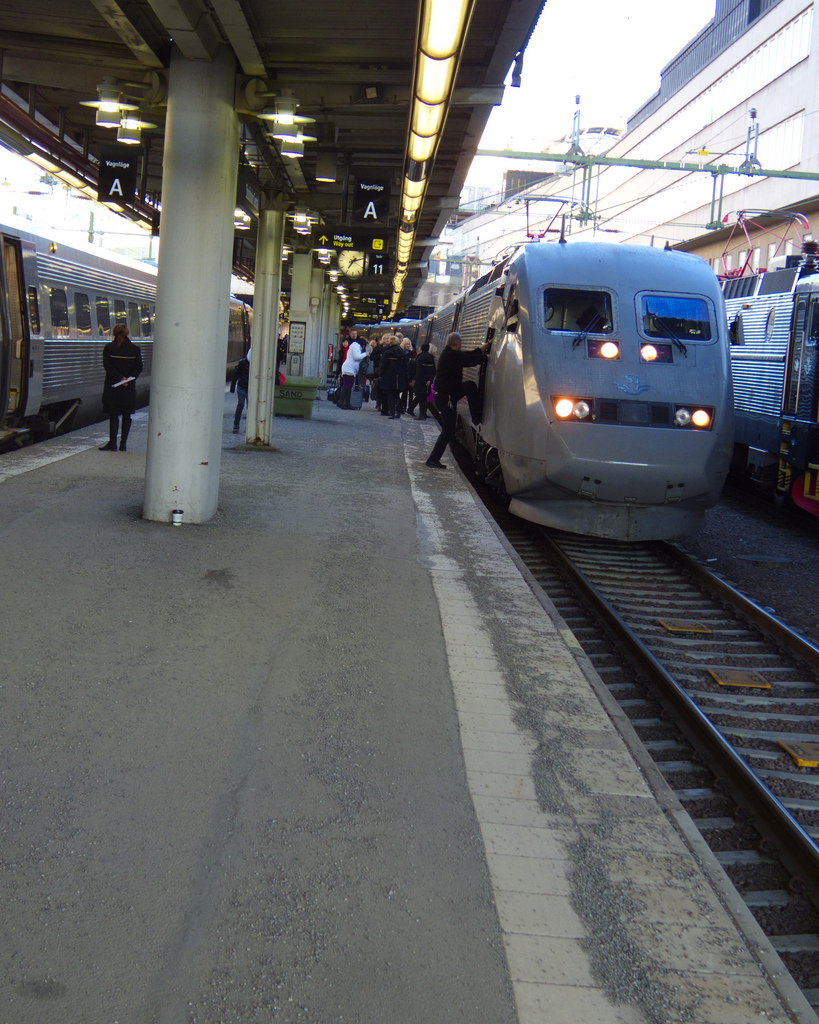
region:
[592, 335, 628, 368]
a headlight on the train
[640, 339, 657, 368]
a headlight on the train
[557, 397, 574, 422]
a headlight on the train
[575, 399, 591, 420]
a headlight on the train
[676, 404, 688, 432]
a headlight on the train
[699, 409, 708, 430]
a headlight on the train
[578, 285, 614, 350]
windshield wiper on train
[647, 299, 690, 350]
windshield wiper on train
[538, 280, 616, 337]
window on front train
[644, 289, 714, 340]
window on front train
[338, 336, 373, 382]
White sweater on a passenger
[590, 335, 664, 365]
Two headlights on the train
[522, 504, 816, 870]
Tracks in front of the train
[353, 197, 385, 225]
The letter A on a sign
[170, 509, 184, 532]
Cup next to the column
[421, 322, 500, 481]
Person boarding the train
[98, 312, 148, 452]
Person standing next to the train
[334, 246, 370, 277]
Clock hanging from ceiling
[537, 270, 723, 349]
Windshields on the train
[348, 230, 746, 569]
long silver train on train tracks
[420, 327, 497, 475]
person boarding train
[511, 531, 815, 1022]
train tracks in front of train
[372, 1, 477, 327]
long yellow light on ceiling of platform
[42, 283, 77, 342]
window on side of train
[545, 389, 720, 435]
headlights on front of train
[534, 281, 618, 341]
window on front of train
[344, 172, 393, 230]
black and white sign hanging from roof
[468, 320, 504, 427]
door on side of train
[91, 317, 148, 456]
person standing in platform dressed in black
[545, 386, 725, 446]
yellow headlights on front of train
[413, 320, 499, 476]
conductor boarding train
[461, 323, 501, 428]
door on side of train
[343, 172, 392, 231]
black and white sign hanging from ceiling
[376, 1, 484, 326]
long yellow light on ceiling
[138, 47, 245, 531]
white post column on train platform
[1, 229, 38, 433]
open door on train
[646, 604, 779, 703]
yellow square blocks on train tracks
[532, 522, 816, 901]
train rails for subway train to move along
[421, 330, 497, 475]
man hopping aboard train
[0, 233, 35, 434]
open door to subway train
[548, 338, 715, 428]
four headlight that are illuminated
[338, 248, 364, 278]
a clock at the train station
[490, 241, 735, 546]
a smooth front of a train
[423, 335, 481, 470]
person stepping onto the train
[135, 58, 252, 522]
a column supporting the roof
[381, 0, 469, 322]
a long row of florescent lights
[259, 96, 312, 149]
a couple of round light fixtures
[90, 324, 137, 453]
a person waiting at the station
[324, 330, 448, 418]
a crowd of people by the train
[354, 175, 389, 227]
a sign denoting the area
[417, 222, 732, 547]
silver rounded train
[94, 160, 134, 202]
black sign with a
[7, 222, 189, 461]
silver metal train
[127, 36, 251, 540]
concrete gray pole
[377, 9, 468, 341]
row of overhead lights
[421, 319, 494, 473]
man climbing on train